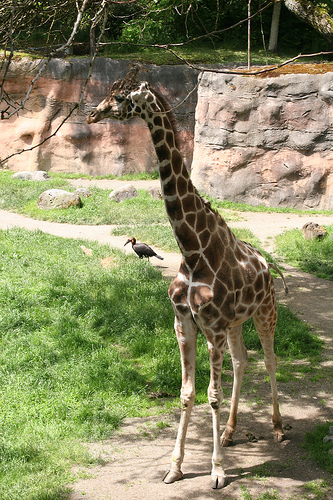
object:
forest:
[1, 0, 333, 51]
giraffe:
[86, 66, 289, 488]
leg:
[206, 339, 226, 491]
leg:
[162, 316, 197, 484]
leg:
[219, 321, 248, 447]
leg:
[254, 310, 285, 445]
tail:
[267, 262, 289, 294]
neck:
[144, 112, 227, 269]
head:
[86, 62, 156, 124]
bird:
[124, 236, 164, 263]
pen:
[1, 59, 332, 500]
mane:
[147, 85, 180, 149]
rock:
[37, 189, 84, 209]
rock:
[108, 183, 137, 201]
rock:
[12, 171, 48, 181]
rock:
[302, 222, 329, 243]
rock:
[146, 187, 160, 201]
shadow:
[6, 257, 332, 499]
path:
[1, 209, 183, 277]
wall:
[0, 59, 333, 210]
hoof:
[211, 476, 225, 488]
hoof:
[162, 467, 183, 484]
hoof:
[273, 431, 285, 442]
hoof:
[219, 435, 231, 447]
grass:
[1, 170, 193, 245]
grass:
[273, 224, 333, 278]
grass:
[1, 226, 181, 499]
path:
[0, 209, 332, 499]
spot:
[164, 198, 184, 221]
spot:
[154, 144, 170, 164]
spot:
[199, 231, 210, 247]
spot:
[219, 228, 230, 247]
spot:
[242, 287, 254, 306]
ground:
[0, 174, 333, 498]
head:
[124, 236, 136, 246]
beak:
[124, 240, 130, 246]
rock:
[74, 189, 92, 199]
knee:
[180, 391, 194, 410]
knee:
[207, 385, 223, 411]